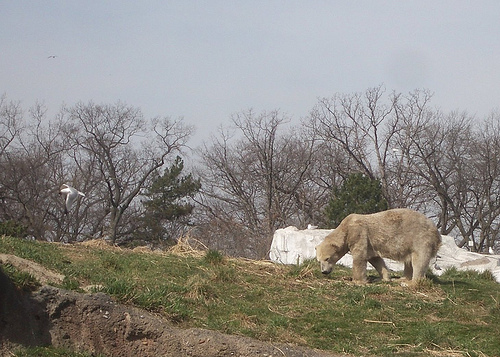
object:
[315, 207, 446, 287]
bear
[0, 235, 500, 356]
field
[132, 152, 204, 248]
tree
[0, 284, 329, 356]
dirt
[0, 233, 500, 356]
ground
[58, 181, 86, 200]
bird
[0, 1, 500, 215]
sky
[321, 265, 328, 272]
nose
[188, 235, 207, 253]
straw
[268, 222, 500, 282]
snow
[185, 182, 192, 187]
leaves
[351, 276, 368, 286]
paw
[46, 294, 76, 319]
rock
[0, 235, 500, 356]
grass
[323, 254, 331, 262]
eye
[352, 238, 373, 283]
legs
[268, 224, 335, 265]
ice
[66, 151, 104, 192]
branch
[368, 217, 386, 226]
fur